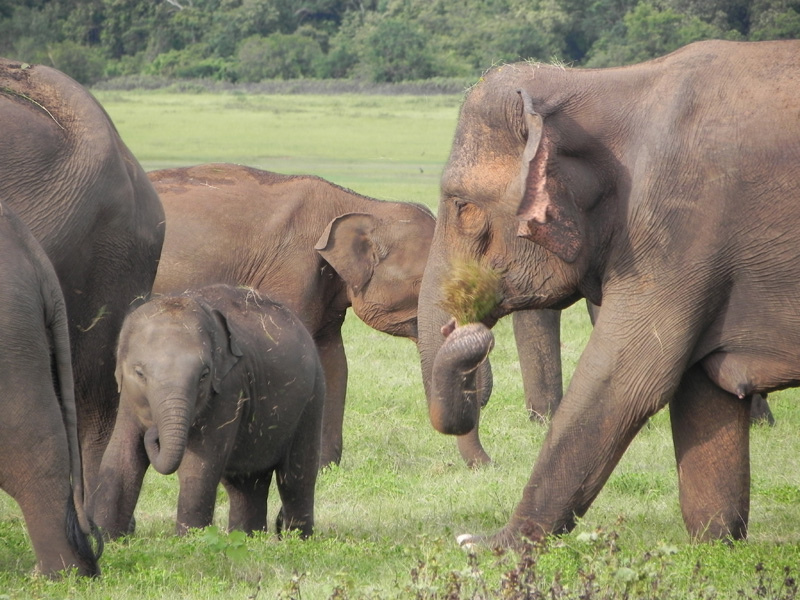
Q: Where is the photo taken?
A: In a field.